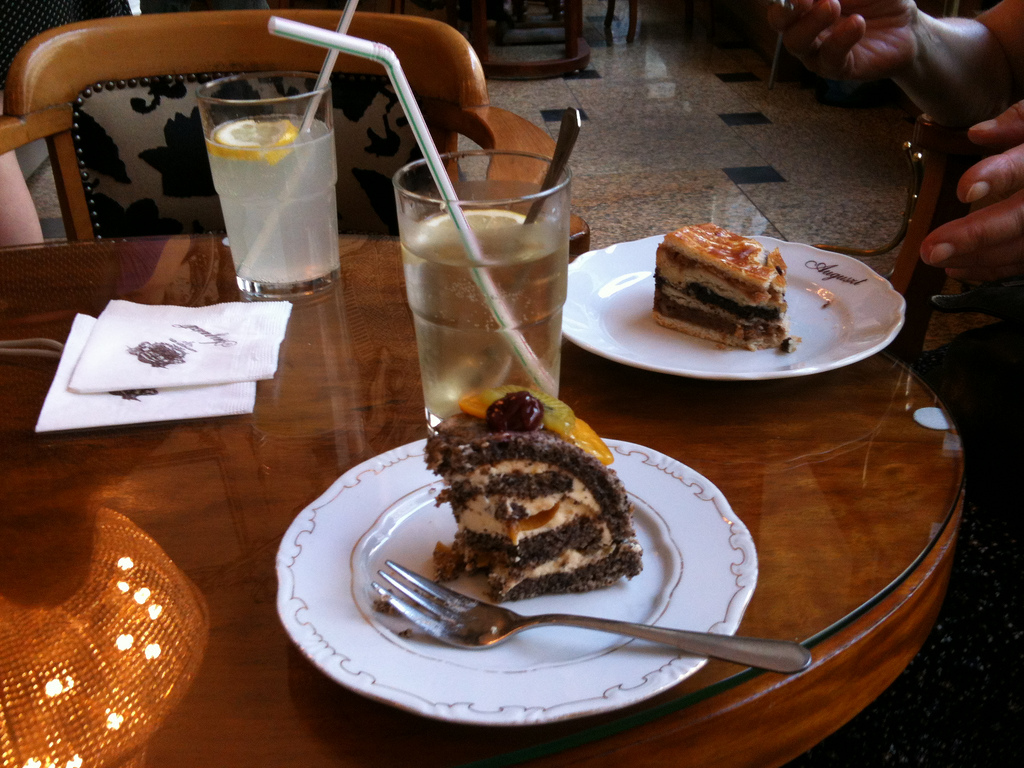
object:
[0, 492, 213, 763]
reflection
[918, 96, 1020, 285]
fingertips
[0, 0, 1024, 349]
floor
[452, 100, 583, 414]
spoon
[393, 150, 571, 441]
glass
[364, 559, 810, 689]
fork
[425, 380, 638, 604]
cake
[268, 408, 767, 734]
plate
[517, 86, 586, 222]
straw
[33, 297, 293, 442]
napkins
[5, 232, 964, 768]
wood table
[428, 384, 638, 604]
dessert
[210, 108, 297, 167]
lemon slice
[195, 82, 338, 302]
drink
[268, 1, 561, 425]
straw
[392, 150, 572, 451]
drink